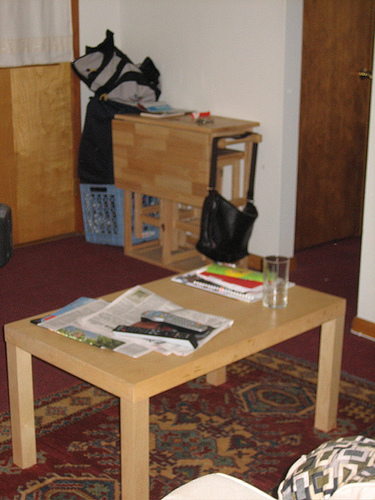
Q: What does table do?
A: Folds.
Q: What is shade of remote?
A: Silver.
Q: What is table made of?
A: Wood.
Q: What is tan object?
A: Table.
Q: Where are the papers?
A: On table.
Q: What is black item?
A: Purse.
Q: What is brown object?
A: Door.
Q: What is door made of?
A: Wood.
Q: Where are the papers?
A: On the table.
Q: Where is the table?
A: On the rug.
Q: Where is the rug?
A: On the ground.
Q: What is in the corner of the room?
A: A blue container.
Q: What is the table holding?
A: Papers and a glass.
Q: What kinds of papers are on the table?
A: Newspapers.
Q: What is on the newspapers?
A: Remotes.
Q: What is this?
A: Table.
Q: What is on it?
A: Glass.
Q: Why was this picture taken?
A: To show the room.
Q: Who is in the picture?
A: No one.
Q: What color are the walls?
A: White.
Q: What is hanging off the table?
A: A purse.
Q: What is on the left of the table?
A: Paper and remotes.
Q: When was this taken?
A: Night time.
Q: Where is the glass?
A: Right side of the table.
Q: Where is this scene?
A: Living room.